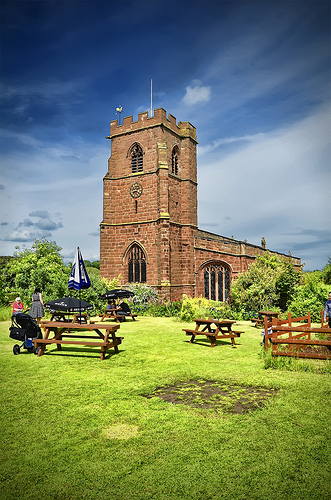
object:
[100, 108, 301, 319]
building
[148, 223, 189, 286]
bricks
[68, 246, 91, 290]
umbrella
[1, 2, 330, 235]
sky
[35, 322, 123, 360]
table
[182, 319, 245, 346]
table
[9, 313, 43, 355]
stroller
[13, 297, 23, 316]
woman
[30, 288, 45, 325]
woman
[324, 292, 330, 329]
man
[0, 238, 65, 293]
bushes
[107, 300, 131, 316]
people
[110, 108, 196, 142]
roof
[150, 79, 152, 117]
pole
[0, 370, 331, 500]
grass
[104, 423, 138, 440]
spot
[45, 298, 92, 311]
umbrella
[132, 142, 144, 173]
window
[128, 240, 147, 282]
window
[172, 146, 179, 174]
window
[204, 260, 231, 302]
window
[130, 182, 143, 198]
clock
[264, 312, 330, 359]
fence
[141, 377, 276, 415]
patch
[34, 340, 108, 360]
bench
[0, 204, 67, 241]
clouds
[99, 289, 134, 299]
umbrella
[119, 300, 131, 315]
person